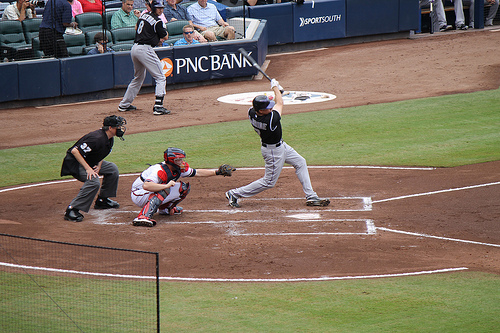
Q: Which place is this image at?
A: It is at the field.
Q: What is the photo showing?
A: It is showing a field.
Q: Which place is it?
A: It is a field.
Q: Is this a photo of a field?
A: Yes, it is showing a field.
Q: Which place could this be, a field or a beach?
A: It is a field.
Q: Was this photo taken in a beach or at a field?
A: It was taken at a field.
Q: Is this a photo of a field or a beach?
A: It is showing a field.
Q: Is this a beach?
A: No, it is a field.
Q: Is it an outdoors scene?
A: Yes, it is outdoors.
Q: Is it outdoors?
A: Yes, it is outdoors.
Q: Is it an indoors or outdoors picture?
A: It is outdoors.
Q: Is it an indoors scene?
A: No, it is outdoors.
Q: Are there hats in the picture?
A: Yes, there is a hat.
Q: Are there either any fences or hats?
A: Yes, there is a hat.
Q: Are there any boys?
A: No, there are no boys.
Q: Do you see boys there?
A: No, there are no boys.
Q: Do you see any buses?
A: No, there are no buses.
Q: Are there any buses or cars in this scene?
A: No, there are no buses or cars.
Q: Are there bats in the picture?
A: Yes, there is a bat.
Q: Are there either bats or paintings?
A: Yes, there is a bat.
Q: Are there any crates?
A: No, there are no crates.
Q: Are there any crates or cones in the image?
A: No, there are no crates or cones.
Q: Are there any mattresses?
A: No, there are no mattresses.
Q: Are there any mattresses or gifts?
A: No, there are no mattresses or gifts.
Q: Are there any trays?
A: No, there are no trays.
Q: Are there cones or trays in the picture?
A: No, there are no trays or cones.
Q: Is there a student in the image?
A: No, there are no students.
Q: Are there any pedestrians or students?
A: No, there are no students or pedestrians.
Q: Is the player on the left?
A: Yes, the player is on the left of the image.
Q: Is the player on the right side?
A: No, the player is on the left of the image.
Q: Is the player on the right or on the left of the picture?
A: The player is on the left of the image.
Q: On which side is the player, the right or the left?
A: The player is on the left of the image.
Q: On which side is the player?
A: The player is on the left of the image.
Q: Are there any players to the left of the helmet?
A: Yes, there is a player to the left of the helmet.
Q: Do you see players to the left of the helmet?
A: Yes, there is a player to the left of the helmet.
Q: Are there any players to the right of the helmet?
A: No, the player is to the left of the helmet.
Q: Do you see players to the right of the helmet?
A: No, the player is to the left of the helmet.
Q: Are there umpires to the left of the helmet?
A: No, there is a player to the left of the helmet.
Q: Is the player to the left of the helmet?
A: Yes, the player is to the left of the helmet.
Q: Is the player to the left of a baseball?
A: No, the player is to the left of the helmet.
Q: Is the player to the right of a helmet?
A: No, the player is to the left of a helmet.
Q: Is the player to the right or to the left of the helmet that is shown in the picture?
A: The player is to the left of the helmet.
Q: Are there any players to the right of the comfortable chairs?
A: Yes, there is a player to the right of the chairs.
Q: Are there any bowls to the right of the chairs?
A: No, there is a player to the right of the chairs.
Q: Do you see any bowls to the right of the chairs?
A: No, there is a player to the right of the chairs.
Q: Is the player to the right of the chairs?
A: Yes, the player is to the right of the chairs.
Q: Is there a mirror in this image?
A: No, there are no mirrors.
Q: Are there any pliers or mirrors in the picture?
A: No, there are no mirrors or pliers.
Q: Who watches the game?
A: The audience watches the game.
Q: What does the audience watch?
A: The audience watches the game.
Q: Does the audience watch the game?
A: Yes, the audience watches the game.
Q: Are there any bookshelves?
A: No, there are no bookshelves.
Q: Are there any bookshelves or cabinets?
A: No, there are no bookshelves or cabinets.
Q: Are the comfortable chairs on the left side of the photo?
A: Yes, the chairs are on the left of the image.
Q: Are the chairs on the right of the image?
A: No, the chairs are on the left of the image.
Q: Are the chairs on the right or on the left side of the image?
A: The chairs are on the left of the image.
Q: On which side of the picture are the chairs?
A: The chairs are on the left of the image.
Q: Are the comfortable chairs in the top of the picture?
A: Yes, the chairs are in the top of the image.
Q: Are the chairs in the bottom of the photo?
A: No, the chairs are in the top of the image.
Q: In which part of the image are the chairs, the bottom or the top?
A: The chairs are in the top of the image.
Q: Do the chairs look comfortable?
A: Yes, the chairs are comfortable.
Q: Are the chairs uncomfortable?
A: No, the chairs are comfortable.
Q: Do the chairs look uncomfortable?
A: No, the chairs are comfortable.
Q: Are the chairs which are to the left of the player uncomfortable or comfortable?
A: The chairs are comfortable.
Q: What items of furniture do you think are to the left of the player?
A: The pieces of furniture are chairs.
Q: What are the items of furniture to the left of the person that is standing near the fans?
A: The pieces of furniture are chairs.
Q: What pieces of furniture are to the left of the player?
A: The pieces of furniture are chairs.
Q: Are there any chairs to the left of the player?
A: Yes, there are chairs to the left of the player.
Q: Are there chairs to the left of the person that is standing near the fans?
A: Yes, there are chairs to the left of the player.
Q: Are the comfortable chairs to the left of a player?
A: Yes, the chairs are to the left of a player.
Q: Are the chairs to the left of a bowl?
A: No, the chairs are to the left of a player.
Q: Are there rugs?
A: No, there are no rugs.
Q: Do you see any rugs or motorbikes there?
A: No, there are no rugs or motorbikes.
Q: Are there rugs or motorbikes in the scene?
A: No, there are no rugs or motorbikes.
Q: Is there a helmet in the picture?
A: Yes, there is a helmet.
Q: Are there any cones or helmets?
A: Yes, there is a helmet.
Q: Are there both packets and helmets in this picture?
A: No, there is a helmet but no packets.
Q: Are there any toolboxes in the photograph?
A: No, there are no toolboxes.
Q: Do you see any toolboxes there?
A: No, there are no toolboxes.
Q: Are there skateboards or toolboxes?
A: No, there are no toolboxes or skateboards.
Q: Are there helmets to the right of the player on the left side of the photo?
A: Yes, there is a helmet to the right of the player.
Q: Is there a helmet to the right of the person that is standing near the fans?
A: Yes, there is a helmet to the right of the player.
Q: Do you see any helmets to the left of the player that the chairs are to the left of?
A: No, the helmet is to the right of the player.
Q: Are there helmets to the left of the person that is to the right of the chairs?
A: No, the helmet is to the right of the player.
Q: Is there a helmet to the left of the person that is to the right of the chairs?
A: No, the helmet is to the right of the player.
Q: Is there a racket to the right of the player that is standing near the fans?
A: No, there is a helmet to the right of the player.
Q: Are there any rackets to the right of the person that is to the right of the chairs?
A: No, there is a helmet to the right of the player.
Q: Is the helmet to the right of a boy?
A: No, the helmet is to the right of a player.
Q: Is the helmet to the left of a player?
A: No, the helmet is to the right of a player.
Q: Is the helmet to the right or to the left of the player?
A: The helmet is to the right of the player.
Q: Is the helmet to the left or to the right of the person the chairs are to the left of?
A: The helmet is to the right of the player.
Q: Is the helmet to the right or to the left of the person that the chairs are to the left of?
A: The helmet is to the right of the player.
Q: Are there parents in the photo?
A: No, there are no parents.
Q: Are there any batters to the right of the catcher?
A: Yes, there is a batter to the right of the catcher.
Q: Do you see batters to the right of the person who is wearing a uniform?
A: Yes, there is a batter to the right of the catcher.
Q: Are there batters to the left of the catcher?
A: No, the batter is to the right of the catcher.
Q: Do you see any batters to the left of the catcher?
A: No, the batter is to the right of the catcher.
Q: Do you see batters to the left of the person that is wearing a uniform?
A: No, the batter is to the right of the catcher.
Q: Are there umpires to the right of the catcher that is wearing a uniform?
A: No, there is a batter to the right of the catcher.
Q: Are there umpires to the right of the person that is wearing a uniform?
A: No, there is a batter to the right of the catcher.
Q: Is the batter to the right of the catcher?
A: Yes, the batter is to the right of the catcher.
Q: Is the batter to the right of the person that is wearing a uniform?
A: Yes, the batter is to the right of the catcher.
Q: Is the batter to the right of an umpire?
A: No, the batter is to the right of the catcher.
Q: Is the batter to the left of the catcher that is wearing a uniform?
A: No, the batter is to the right of the catcher.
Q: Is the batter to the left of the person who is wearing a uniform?
A: No, the batter is to the right of the catcher.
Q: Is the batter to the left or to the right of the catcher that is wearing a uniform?
A: The batter is to the right of the catcher.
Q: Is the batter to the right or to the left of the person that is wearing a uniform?
A: The batter is to the right of the catcher.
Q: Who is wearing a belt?
A: The batter is wearing a belt.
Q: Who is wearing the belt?
A: The batter is wearing a belt.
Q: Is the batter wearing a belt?
A: Yes, the batter is wearing a belt.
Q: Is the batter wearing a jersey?
A: No, the batter is wearing a belt.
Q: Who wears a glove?
A: The batter wears a glove.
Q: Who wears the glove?
A: The batter wears a glove.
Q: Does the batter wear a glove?
A: Yes, the batter wears a glove.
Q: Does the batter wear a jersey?
A: No, the batter wears a glove.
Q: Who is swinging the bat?
A: The batter is swinging the bat.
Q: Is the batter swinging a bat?
A: Yes, the batter is swinging a bat.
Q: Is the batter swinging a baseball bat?
A: No, the batter is swinging a bat.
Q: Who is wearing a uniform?
A: The catcher is wearing a uniform.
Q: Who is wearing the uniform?
A: The catcher is wearing a uniform.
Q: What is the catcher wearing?
A: The catcher is wearing a uniform.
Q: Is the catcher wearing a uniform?
A: Yes, the catcher is wearing a uniform.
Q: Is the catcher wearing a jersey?
A: No, the catcher is wearing a uniform.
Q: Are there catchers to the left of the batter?
A: Yes, there is a catcher to the left of the batter.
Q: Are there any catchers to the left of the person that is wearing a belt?
A: Yes, there is a catcher to the left of the batter.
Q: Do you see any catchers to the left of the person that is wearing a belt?
A: Yes, there is a catcher to the left of the batter.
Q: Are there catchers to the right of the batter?
A: No, the catcher is to the left of the batter.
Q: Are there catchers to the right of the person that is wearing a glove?
A: No, the catcher is to the left of the batter.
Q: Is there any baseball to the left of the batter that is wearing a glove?
A: No, there is a catcher to the left of the batter.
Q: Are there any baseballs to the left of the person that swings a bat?
A: No, there is a catcher to the left of the batter.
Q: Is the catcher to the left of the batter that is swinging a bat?
A: Yes, the catcher is to the left of the batter.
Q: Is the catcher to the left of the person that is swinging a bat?
A: Yes, the catcher is to the left of the batter.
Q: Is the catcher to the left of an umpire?
A: No, the catcher is to the left of the batter.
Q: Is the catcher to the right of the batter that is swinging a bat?
A: No, the catcher is to the left of the batter.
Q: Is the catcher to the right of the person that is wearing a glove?
A: No, the catcher is to the left of the batter.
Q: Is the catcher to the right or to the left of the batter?
A: The catcher is to the left of the batter.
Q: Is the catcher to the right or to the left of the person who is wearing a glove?
A: The catcher is to the left of the batter.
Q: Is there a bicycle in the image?
A: No, there are no bicycles.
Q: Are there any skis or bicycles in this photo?
A: No, there are no bicycles or skis.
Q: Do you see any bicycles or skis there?
A: No, there are no bicycles or skis.